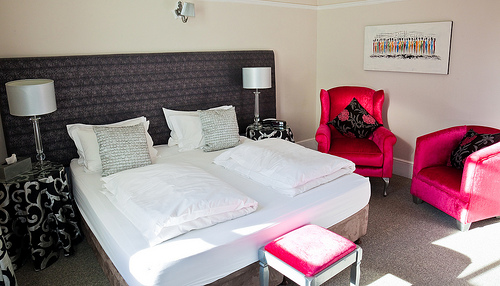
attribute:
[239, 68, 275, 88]
lamp — white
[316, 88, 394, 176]
chair — red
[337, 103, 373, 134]
pillow — square, floral, black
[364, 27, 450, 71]
picture — colorful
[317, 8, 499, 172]
wall — white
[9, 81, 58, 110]
lamp — small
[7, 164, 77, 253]
table — round, small, black, silver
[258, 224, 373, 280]
stool — red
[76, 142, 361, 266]
bed — large, white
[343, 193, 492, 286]
carpet — beige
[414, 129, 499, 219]
chair — dark pink, red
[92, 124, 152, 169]
pillow — gray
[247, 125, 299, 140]
tablecloth — black, silver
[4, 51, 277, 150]
headboard — grey